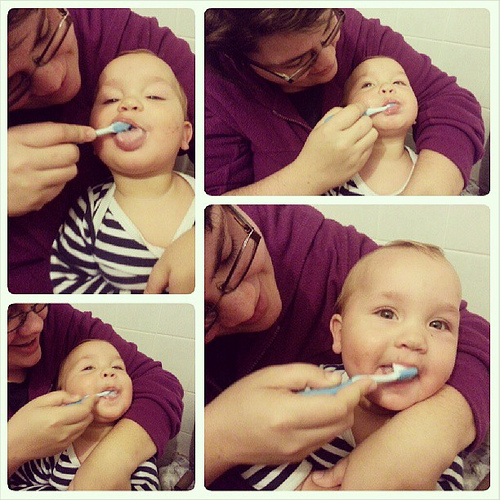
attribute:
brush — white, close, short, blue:
[308, 368, 417, 406]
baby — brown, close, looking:
[287, 235, 471, 489]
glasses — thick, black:
[265, 9, 347, 86]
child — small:
[238, 236, 466, 497]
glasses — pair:
[6, 8, 72, 105]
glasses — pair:
[201, 206, 267, 337]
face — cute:
[325, 238, 457, 413]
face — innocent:
[318, 238, 461, 408]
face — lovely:
[339, 57, 420, 133]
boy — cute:
[233, 237, 456, 498]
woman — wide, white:
[205, 6, 485, 196]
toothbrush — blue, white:
[91, 121, 131, 137]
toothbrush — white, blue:
[318, 103, 393, 123]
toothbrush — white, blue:
[63, 390, 110, 404]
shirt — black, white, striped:
[46, 169, 194, 289]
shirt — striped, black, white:
[327, 147, 417, 197]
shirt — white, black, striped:
[16, 440, 166, 491]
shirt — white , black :
[53, 196, 199, 296]